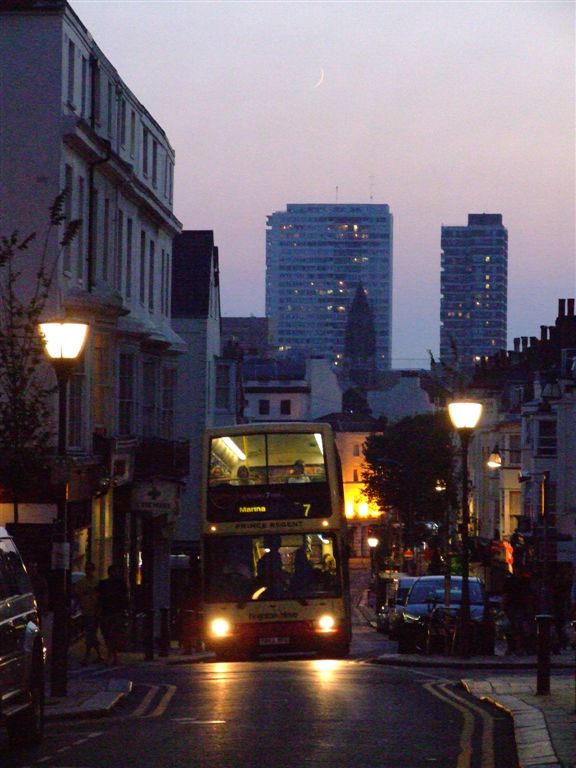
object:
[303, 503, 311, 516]
number 7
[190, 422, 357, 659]
bus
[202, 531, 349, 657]
bottom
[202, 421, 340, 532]
top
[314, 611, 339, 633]
headlights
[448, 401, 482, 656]
street lamp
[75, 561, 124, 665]
people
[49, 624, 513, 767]
street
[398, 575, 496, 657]
car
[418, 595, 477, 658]
bikes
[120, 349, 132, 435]
window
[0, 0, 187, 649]
building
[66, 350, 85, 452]
window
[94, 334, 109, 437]
window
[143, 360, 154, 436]
window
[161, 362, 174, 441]
window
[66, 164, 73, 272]
window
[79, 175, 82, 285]
window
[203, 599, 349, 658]
front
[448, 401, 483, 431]
lamp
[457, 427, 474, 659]
lightpost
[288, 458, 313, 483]
people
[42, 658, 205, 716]
sidewalk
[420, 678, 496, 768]
lines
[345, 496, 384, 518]
lights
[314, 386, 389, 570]
building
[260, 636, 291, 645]
license plate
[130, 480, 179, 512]
sign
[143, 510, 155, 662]
post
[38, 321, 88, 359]
light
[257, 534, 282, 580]
person